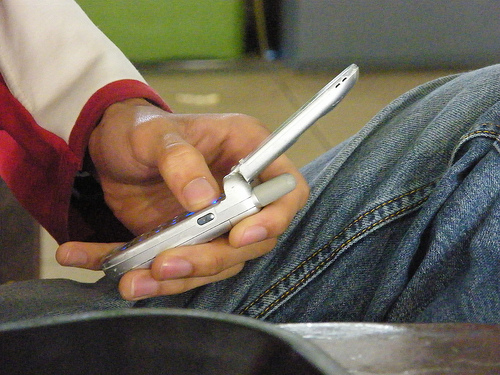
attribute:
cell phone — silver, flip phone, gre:
[91, 65, 360, 280]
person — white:
[1, 2, 499, 320]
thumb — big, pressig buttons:
[155, 143, 222, 211]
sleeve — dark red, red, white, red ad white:
[2, 4, 170, 250]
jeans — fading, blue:
[133, 59, 500, 317]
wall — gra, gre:
[278, 4, 497, 67]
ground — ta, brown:
[148, 60, 452, 155]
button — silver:
[195, 211, 214, 224]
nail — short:
[177, 175, 217, 208]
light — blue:
[103, 187, 225, 255]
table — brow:
[2, 273, 492, 366]